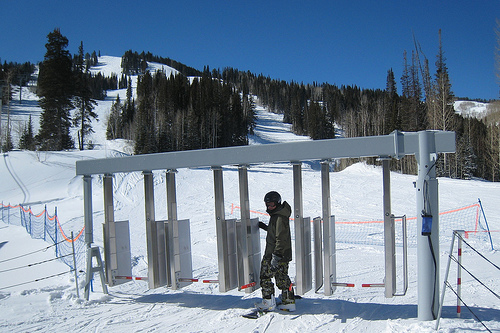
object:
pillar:
[164, 169, 196, 289]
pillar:
[412, 129, 441, 321]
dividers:
[76, 129, 456, 321]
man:
[253, 190, 296, 312]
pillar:
[168, 167, 195, 290]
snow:
[0, 54, 500, 333]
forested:
[0, 46, 499, 183]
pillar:
[102, 173, 133, 287]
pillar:
[382, 155, 397, 297]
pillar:
[237, 163, 262, 292]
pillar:
[213, 164, 238, 292]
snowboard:
[242, 300, 276, 320]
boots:
[254, 300, 296, 312]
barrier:
[0, 197, 495, 299]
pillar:
[142, 170, 170, 291]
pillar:
[292, 160, 314, 297]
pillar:
[81, 173, 95, 249]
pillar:
[312, 159, 337, 296]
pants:
[259, 257, 295, 304]